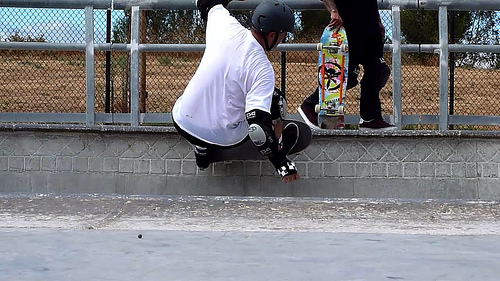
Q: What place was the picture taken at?
A: It was taken at the field.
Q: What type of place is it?
A: It is a field.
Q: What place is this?
A: It is a field.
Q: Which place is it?
A: It is a field.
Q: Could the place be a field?
A: Yes, it is a field.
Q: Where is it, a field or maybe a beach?
A: It is a field.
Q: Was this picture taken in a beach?
A: No, the picture was taken in a field.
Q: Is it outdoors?
A: Yes, it is outdoors.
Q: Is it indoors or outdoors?
A: It is outdoors.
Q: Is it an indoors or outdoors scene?
A: It is outdoors.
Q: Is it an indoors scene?
A: No, it is outdoors.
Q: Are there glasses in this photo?
A: No, there are no glasses.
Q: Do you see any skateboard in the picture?
A: Yes, there is a skateboard.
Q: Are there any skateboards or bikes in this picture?
A: Yes, there is a skateboard.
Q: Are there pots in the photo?
A: No, there are no pots.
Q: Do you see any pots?
A: No, there are no pots.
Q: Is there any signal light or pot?
A: No, there are no pots or traffic lights.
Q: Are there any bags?
A: No, there are no bags.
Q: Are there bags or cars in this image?
A: No, there are no bags or cars.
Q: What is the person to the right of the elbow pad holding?
A: The person is holding the skateboard.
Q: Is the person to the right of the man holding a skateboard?
A: Yes, the person is holding a skateboard.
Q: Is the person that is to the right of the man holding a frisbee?
A: No, the person is holding a skateboard.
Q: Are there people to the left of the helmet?
A: No, the person is to the right of the helmet.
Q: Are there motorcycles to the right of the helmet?
A: No, there is a person to the right of the helmet.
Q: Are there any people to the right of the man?
A: Yes, there is a person to the right of the man.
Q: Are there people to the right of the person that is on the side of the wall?
A: Yes, there is a person to the right of the man.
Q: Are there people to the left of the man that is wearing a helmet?
A: No, the person is to the right of the man.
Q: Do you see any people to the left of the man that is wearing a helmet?
A: No, the person is to the right of the man.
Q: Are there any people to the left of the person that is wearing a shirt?
A: No, the person is to the right of the man.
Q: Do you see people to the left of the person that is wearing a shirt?
A: No, the person is to the right of the man.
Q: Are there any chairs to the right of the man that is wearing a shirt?
A: No, there is a person to the right of the man.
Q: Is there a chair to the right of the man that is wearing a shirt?
A: No, there is a person to the right of the man.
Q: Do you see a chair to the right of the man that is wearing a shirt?
A: No, there is a person to the right of the man.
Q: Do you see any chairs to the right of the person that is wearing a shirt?
A: No, there is a person to the right of the man.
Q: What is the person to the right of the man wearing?
A: The person is wearing pants.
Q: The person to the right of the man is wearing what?
A: The person is wearing pants.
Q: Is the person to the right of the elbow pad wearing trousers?
A: Yes, the person is wearing trousers.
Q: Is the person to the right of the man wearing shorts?
A: No, the person is wearing trousers.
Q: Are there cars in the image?
A: No, there are no cars.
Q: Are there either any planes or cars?
A: No, there are no cars or planes.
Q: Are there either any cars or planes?
A: No, there are no cars or planes.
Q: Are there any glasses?
A: No, there are no glasses.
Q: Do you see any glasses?
A: No, there are no glasses.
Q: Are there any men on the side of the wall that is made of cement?
A: Yes, there is a man on the side of the wall.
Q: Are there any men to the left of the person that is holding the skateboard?
A: Yes, there is a man to the left of the person.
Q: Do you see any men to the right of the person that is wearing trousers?
A: No, the man is to the left of the person.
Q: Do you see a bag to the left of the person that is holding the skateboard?
A: No, there is a man to the left of the person.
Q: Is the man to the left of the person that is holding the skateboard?
A: Yes, the man is to the left of the person.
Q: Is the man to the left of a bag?
A: No, the man is to the left of the person.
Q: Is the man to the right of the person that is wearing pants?
A: No, the man is to the left of the person.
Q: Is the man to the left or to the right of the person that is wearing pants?
A: The man is to the left of the person.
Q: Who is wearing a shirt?
A: The man is wearing a shirt.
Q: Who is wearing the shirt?
A: The man is wearing a shirt.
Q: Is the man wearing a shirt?
A: Yes, the man is wearing a shirt.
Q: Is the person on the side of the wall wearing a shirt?
A: Yes, the man is wearing a shirt.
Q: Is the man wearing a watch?
A: No, the man is wearing a shirt.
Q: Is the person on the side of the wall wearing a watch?
A: No, the man is wearing a shirt.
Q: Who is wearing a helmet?
A: The man is wearing a helmet.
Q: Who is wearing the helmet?
A: The man is wearing a helmet.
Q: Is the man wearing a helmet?
A: Yes, the man is wearing a helmet.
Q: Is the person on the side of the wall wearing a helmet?
A: Yes, the man is wearing a helmet.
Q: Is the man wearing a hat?
A: No, the man is wearing a helmet.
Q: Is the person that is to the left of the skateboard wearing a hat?
A: No, the man is wearing a helmet.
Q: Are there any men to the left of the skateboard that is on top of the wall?
A: Yes, there is a man to the left of the skateboard.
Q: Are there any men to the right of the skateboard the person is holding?
A: No, the man is to the left of the skateboard.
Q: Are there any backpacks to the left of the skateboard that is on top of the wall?
A: No, there is a man to the left of the skateboard.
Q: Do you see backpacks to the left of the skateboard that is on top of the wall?
A: No, there is a man to the left of the skateboard.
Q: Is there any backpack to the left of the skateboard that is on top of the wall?
A: No, there is a man to the left of the skateboard.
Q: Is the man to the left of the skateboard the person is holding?
A: Yes, the man is to the left of the skateboard.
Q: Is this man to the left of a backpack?
A: No, the man is to the left of the skateboard.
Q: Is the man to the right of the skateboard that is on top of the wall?
A: No, the man is to the left of the skateboard.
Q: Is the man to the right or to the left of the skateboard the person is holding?
A: The man is to the left of the skateboard.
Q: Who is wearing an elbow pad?
A: The man is wearing an elbow pad.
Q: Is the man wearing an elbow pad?
A: Yes, the man is wearing an elbow pad.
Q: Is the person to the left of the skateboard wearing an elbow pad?
A: Yes, the man is wearing an elbow pad.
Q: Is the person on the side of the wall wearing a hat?
A: No, the man is wearing an elbow pad.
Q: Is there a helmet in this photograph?
A: Yes, there is a helmet.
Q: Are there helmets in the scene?
A: Yes, there is a helmet.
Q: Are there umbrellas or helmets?
A: Yes, there is a helmet.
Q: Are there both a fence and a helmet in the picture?
A: Yes, there are both a helmet and a fence.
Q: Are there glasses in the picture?
A: No, there are no glasses.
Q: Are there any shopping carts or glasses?
A: No, there are no glasses or shopping carts.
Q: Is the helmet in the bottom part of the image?
A: No, the helmet is in the top of the image.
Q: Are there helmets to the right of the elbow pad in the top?
A: Yes, there is a helmet to the right of the elbow pad.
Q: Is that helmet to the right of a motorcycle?
A: No, the helmet is to the right of the elbow pad.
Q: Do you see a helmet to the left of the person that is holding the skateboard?
A: Yes, there is a helmet to the left of the person.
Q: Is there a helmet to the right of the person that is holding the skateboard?
A: No, the helmet is to the left of the person.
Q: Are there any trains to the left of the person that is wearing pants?
A: No, there is a helmet to the left of the person.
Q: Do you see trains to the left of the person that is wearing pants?
A: No, there is a helmet to the left of the person.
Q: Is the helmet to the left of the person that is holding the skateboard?
A: Yes, the helmet is to the left of the person.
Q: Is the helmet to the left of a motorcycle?
A: No, the helmet is to the left of the person.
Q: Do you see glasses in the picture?
A: No, there are no glasses.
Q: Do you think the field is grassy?
A: Yes, the field is grassy.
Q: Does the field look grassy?
A: Yes, the field is grassy.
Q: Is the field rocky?
A: No, the field is grassy.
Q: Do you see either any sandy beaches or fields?
A: No, there is a field but it is grassy.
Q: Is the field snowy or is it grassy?
A: The field is grassy.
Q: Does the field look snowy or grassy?
A: The field is grassy.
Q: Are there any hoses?
A: No, there are no hoses.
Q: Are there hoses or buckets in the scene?
A: No, there are no hoses or buckets.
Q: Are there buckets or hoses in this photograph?
A: No, there are no hoses or buckets.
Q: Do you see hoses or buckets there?
A: No, there are no hoses or buckets.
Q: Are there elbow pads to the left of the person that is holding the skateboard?
A: Yes, there is an elbow pad to the left of the person.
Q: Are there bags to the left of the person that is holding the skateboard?
A: No, there is an elbow pad to the left of the person.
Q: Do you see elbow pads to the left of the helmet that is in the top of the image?
A: Yes, there is an elbow pad to the left of the helmet.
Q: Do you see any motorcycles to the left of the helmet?
A: No, there is an elbow pad to the left of the helmet.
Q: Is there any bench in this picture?
A: No, there are no benches.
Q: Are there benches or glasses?
A: No, there are no benches or glasses.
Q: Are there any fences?
A: Yes, there is a fence.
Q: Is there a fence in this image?
A: Yes, there is a fence.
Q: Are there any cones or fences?
A: Yes, there is a fence.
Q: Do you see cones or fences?
A: Yes, there is a fence.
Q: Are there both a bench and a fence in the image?
A: No, there is a fence but no benches.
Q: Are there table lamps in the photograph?
A: No, there are no table lamps.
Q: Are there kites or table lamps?
A: No, there are no table lamps or kites.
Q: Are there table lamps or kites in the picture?
A: No, there are no table lamps or kites.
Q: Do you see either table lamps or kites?
A: No, there are no table lamps or kites.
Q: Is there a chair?
A: No, there are no chairs.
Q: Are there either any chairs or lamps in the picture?
A: No, there are no chairs or lamps.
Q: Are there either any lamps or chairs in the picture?
A: No, there are no chairs or lamps.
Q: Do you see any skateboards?
A: Yes, there is a skateboard.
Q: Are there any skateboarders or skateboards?
A: Yes, there is a skateboard.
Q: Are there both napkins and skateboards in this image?
A: No, there is a skateboard but no napkins.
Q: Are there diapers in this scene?
A: No, there are no diapers.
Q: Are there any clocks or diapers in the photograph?
A: No, there are no diapers or clocks.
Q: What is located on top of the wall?
A: The skateboard is on top of the wall.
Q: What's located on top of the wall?
A: The skateboard is on top of the wall.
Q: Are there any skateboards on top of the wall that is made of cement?
A: Yes, there is a skateboard on top of the wall.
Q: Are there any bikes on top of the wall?
A: No, there is a skateboard on top of the wall.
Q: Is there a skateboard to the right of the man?
A: Yes, there is a skateboard to the right of the man.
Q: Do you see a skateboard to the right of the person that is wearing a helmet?
A: Yes, there is a skateboard to the right of the man.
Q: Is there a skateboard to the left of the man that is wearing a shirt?
A: No, the skateboard is to the right of the man.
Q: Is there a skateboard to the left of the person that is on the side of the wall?
A: No, the skateboard is to the right of the man.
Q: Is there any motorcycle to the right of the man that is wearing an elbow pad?
A: No, there is a skateboard to the right of the man.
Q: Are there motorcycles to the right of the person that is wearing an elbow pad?
A: No, there is a skateboard to the right of the man.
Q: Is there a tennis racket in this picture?
A: No, there are no rackets.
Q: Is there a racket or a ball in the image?
A: No, there are no rackets or balls.